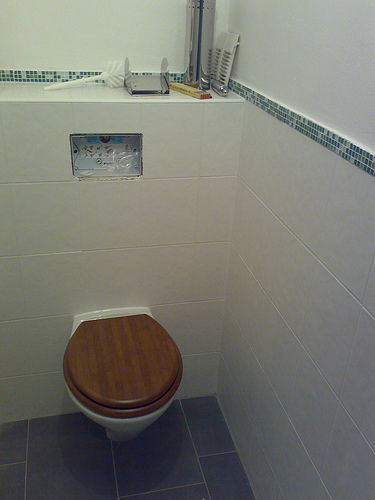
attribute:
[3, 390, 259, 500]
floor — tiled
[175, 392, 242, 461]
tile — gray, grey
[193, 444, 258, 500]
tile — gray, grey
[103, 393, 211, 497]
tile — gray, grey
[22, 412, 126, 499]
tile — gray, grey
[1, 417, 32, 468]
tile — gray, grey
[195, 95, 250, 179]
tile — off white, white, large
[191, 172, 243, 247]
tile — off white, white, large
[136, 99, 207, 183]
tile — off white, white, large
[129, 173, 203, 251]
tile — off white, white, large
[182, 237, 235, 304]
tile — off white, white, large